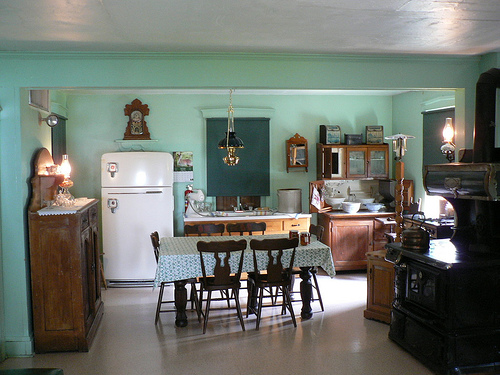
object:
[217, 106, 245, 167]
chandelier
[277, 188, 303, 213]
metal pot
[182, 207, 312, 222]
counter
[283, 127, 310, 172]
mirror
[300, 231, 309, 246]
jars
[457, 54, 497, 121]
pipe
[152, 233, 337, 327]
dining table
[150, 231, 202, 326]
chair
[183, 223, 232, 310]
chair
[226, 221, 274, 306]
chair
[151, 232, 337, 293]
cloth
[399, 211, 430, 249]
kettle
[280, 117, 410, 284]
sideboard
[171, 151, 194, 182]
calender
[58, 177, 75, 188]
oil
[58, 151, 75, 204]
oil lamp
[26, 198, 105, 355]
cabinet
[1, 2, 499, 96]
ceiling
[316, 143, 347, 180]
cabinet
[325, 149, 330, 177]
door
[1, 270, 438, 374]
linoleum floor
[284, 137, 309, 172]
mirror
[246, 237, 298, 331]
chair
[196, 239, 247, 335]
chair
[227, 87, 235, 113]
fixture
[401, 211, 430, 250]
kerosene lantern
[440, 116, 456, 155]
lamp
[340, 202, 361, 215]
bowl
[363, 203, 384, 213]
bowl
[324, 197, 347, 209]
bowl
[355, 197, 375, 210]
bowl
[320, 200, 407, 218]
shelf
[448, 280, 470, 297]
wood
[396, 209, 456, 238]
stove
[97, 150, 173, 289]
fridge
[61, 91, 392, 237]
wall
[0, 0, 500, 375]
kitchen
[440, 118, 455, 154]
oil lamp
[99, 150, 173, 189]
freezer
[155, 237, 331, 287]
design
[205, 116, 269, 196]
shade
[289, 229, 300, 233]
lids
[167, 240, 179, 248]
dots